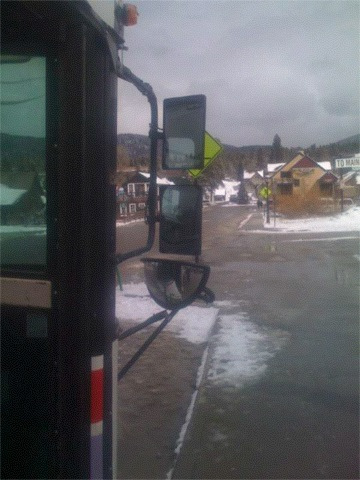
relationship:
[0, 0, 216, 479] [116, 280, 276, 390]
bus driving through slush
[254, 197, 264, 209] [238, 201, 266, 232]
couple on sidewalk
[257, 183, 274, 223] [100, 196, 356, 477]
caution sign on street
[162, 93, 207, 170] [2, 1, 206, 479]
mirror on bus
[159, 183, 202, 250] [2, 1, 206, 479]
mirror on bus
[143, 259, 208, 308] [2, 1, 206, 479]
mirror on bus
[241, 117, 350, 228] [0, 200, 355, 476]
houses on street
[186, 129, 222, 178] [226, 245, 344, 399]
sign on street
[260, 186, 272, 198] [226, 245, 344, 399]
sign on street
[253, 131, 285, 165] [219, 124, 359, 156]
trees on hills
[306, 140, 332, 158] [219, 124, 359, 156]
trees on hills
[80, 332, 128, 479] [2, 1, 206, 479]
design on bus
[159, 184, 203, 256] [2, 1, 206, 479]
mirror on bus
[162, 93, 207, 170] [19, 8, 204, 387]
mirror on bus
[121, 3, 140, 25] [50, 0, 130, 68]
light on roof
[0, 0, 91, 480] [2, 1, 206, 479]
bus door of bus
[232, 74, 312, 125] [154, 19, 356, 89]
cloud in sky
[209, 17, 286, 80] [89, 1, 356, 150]
clods in sky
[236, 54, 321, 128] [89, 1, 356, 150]
clouds in sky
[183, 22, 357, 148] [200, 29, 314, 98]
clouds in sky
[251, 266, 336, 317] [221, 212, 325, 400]
water on street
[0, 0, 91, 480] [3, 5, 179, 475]
bus door on bus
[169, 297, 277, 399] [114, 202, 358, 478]
snow on road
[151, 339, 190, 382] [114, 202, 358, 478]
ice on road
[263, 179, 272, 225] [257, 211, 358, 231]
street light beside sidewalk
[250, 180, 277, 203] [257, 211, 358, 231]
sign beside sidewalk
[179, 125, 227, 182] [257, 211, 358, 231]
sign beside sidewalk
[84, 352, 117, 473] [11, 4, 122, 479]
stripe beside door